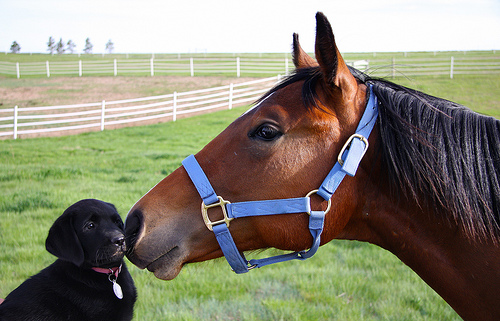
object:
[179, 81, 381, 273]
bridle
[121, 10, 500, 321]
horse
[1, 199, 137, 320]
dog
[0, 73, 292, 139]
fence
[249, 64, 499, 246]
mane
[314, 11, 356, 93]
ear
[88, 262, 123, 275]
collar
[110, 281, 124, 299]
tag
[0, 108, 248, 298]
grass